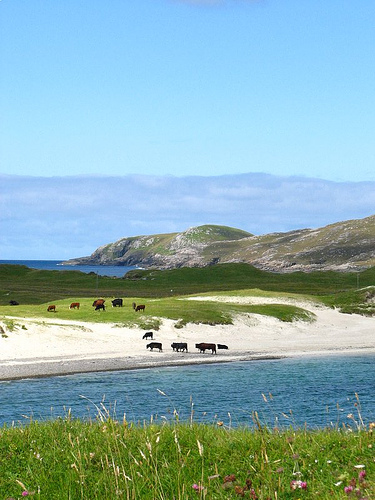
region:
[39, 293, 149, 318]
cattle grazing on the grass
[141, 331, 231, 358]
cattle on the sand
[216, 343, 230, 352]
black cow laying in the sand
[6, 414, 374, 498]
grass on the embankment in the foreground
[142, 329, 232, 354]
group of black cows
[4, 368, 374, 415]
ripples in the water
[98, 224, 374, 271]
mountains between the bodies of water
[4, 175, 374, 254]
mountains in the distance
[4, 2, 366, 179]
blue skies above the mountains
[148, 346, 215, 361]
shadows on the sand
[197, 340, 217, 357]
Large animal standing on the sand.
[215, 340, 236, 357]
Large animal laying on the sand.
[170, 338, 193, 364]
Large animal standing on the sand.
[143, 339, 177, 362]
Large animal standing on sand.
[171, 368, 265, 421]
Blue water in front of animals.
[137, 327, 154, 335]
Large animal standing on sand.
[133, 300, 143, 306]
Large animal standing in grass.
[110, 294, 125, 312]
Large black animal standing in grass.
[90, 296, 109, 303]
Large brown animal standing in grass.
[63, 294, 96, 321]
Brown animal standing in grass.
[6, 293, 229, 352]
Cattle walking across mountain range.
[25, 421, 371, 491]
Green grass with pink flowers.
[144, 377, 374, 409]
Blue water rippling slightly.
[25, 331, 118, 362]
White sandy beaches on mountain.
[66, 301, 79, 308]
Brown cow with white head.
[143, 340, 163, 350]
Black cow walking on beach.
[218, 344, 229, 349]
Black cow is sitting on beach.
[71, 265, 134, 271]
Blue waters on other side of land.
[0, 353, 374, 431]
Gentle blue expanse of water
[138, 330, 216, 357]
Cows standing in the sand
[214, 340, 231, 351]
Cow laying in the sand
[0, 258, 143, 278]
Expanse of water in the distance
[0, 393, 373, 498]
Grass with pink flowering plants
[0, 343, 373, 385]
Long straight and gentle shoreline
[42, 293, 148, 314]
Cows grazing in the grass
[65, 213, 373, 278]
Hill covered with rock and little vegetation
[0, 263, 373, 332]
Expansive grassland background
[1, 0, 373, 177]
Clear blue sky background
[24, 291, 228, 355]
Cows on an island.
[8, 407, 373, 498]
A grassy area near the water.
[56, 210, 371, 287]
Grassy hills on the island type area.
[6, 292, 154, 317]
Cows in the grass.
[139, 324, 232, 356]
Cows on the sand by the water.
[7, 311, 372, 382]
A beach.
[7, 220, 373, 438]
Water on both sides of the land.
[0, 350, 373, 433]
A body of water with grass on one side and sand on the other.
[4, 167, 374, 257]
A bank of low clouds in the sky.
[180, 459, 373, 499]
Small purple flowers in the grass.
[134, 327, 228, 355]
cattle on white sandy shore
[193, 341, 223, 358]
A large black cow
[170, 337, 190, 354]
A large black cow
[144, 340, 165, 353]
A large black cow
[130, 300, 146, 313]
Two brown cows grazing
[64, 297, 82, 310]
A large brown cow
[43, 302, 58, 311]
A large brown cow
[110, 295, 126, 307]
A large black cow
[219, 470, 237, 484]
A small purple thistle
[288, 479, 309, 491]
A bunch of pink flowers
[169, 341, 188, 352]
a black cow in distance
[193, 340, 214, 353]
a black cow in distance